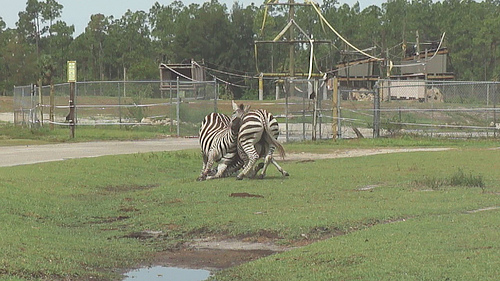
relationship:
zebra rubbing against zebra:
[195, 99, 251, 181] [226, 104, 290, 179]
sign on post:
[64, 58, 78, 83] [68, 82, 77, 138]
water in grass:
[121, 259, 214, 279] [1, 130, 499, 278]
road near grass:
[0, 129, 331, 168] [1, 130, 499, 278]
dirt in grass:
[232, 189, 267, 204] [1, 130, 499, 278]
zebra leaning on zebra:
[195, 99, 251, 181] [226, 104, 290, 179]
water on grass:
[121, 259, 214, 279] [1, 130, 499, 278]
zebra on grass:
[195, 99, 251, 181] [1, 130, 499, 278]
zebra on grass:
[226, 104, 290, 179] [1, 130, 499, 278]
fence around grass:
[12, 79, 499, 146] [1, 130, 499, 278]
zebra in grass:
[195, 99, 251, 181] [1, 130, 499, 278]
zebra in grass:
[226, 104, 290, 179] [1, 130, 499, 278]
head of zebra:
[227, 98, 251, 136] [195, 99, 251, 181]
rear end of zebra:
[240, 110, 279, 142] [226, 104, 290, 179]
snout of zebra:
[229, 117, 243, 140] [195, 99, 251, 181]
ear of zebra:
[229, 99, 241, 113] [195, 99, 251, 181]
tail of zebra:
[260, 116, 286, 160] [226, 104, 290, 179]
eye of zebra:
[232, 110, 239, 117] [195, 99, 251, 181]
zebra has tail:
[226, 104, 290, 179] [260, 116, 286, 160]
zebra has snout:
[195, 99, 251, 181] [229, 117, 243, 140]